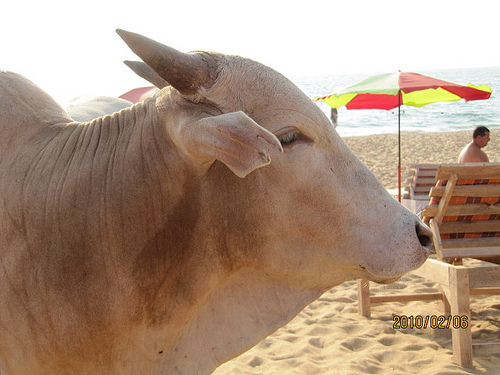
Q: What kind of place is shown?
A: It is a beach.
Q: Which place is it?
A: It is a beach.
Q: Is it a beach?
A: Yes, it is a beach.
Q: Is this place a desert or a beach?
A: It is a beach.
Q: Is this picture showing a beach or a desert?
A: It is showing a beach.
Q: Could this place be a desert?
A: No, it is a beach.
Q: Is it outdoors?
A: Yes, it is outdoors.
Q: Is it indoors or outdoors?
A: It is outdoors.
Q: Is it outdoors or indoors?
A: It is outdoors.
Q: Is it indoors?
A: No, it is outdoors.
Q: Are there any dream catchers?
A: No, there are no dream catchers.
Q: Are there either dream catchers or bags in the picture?
A: No, there are no dream catchers or bags.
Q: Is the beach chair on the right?
A: Yes, the beach chair is on the right of the image.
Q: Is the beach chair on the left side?
A: No, the beach chair is on the right of the image.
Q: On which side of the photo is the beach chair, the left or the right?
A: The beach chair is on the right of the image.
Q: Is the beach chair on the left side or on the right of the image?
A: The beach chair is on the right of the image.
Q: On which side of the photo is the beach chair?
A: The beach chair is on the right of the image.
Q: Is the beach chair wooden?
A: Yes, the beach chair is wooden.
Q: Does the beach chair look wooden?
A: Yes, the beach chair is wooden.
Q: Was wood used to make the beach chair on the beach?
A: Yes, the beach chair is made of wood.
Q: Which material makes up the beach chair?
A: The beach chair is made of wood.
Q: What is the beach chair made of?
A: The beach chair is made of wood.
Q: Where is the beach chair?
A: The beach chair is on the beach.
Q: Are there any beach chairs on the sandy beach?
A: Yes, there is a beach chair on the beach.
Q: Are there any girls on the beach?
A: No, there is a beach chair on the beach.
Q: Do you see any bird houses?
A: No, there are no bird houses.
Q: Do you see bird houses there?
A: No, there are no bird houses.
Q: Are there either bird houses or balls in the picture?
A: No, there are no bird houses or balls.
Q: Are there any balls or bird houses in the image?
A: No, there are no bird houses or balls.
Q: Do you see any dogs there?
A: No, there are no dogs.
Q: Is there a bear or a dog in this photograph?
A: No, there are no dogs or bears.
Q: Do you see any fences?
A: No, there are no fences.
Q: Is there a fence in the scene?
A: No, there are no fences.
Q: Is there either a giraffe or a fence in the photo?
A: No, there are no fences or giraffes.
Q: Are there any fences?
A: No, there are no fences.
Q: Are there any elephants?
A: No, there are no elephants.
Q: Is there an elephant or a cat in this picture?
A: No, there are no elephants or cats.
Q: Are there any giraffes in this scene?
A: No, there are no giraffes.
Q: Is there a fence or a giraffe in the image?
A: No, there are no giraffes or fences.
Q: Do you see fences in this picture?
A: No, there are no fences.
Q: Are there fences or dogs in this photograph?
A: No, there are no fences or dogs.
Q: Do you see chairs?
A: Yes, there is a chair.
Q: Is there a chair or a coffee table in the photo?
A: Yes, there is a chair.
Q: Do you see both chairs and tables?
A: No, there is a chair but no tables.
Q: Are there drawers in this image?
A: No, there are no drawers.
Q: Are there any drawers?
A: No, there are no drawers.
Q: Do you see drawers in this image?
A: No, there are no drawers.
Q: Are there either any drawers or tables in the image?
A: No, there are no drawers or tables.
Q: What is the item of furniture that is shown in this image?
A: The piece of furniture is a chair.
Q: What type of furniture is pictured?
A: The furniture is a chair.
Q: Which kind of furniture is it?
A: The piece of furniture is a chair.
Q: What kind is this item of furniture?
A: This is a chair.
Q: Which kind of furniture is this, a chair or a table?
A: This is a chair.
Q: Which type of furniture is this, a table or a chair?
A: This is a chair.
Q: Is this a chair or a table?
A: This is a chair.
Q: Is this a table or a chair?
A: This is a chair.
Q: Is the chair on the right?
A: Yes, the chair is on the right of the image.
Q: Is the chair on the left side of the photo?
A: No, the chair is on the right of the image.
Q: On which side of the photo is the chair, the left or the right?
A: The chair is on the right of the image.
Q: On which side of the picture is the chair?
A: The chair is on the right of the image.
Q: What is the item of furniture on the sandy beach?
A: The piece of furniture is a chair.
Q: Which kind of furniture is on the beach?
A: The piece of furniture is a chair.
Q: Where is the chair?
A: The chair is on the beach.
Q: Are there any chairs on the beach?
A: Yes, there is a chair on the beach.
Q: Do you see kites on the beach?
A: No, there is a chair on the beach.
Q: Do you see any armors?
A: No, there are no armors.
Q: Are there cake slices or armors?
A: No, there are no armors or cake slices.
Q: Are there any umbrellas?
A: Yes, there is an umbrella.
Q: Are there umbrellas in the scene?
A: Yes, there is an umbrella.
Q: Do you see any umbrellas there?
A: Yes, there is an umbrella.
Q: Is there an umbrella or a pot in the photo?
A: Yes, there is an umbrella.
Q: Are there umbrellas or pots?
A: Yes, there is an umbrella.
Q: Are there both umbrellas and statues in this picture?
A: No, there is an umbrella but no statues.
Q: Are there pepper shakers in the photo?
A: No, there are no pepper shakers.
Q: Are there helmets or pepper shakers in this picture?
A: No, there are no pepper shakers or helmets.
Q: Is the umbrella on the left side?
A: No, the umbrella is on the right of the image.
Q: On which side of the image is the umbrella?
A: The umbrella is on the right of the image.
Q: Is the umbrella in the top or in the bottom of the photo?
A: The umbrella is in the top of the image.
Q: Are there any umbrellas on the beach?
A: Yes, there is an umbrella on the beach.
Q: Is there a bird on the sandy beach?
A: No, there is an umbrella on the beach.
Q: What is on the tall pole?
A: The umbrella is on the pole.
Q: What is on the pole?
A: The umbrella is on the pole.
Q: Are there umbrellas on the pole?
A: Yes, there is an umbrella on the pole.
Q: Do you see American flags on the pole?
A: No, there is an umbrella on the pole.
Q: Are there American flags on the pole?
A: No, there is an umbrella on the pole.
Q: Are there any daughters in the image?
A: No, there are no daughters.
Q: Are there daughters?
A: No, there are no daughters.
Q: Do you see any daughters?
A: No, there are no daughters.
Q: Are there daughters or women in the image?
A: No, there are no daughters or women.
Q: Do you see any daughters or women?
A: No, there are no daughters or women.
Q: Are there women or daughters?
A: No, there are no daughters or women.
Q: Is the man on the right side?
A: Yes, the man is on the right of the image.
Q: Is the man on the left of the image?
A: No, the man is on the right of the image.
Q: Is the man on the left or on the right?
A: The man is on the right of the image.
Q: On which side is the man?
A: The man is on the right of the image.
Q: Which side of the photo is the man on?
A: The man is on the right of the image.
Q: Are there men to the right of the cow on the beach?
A: Yes, there is a man to the right of the cow.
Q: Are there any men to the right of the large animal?
A: Yes, there is a man to the right of the cow.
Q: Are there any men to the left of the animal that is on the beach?
A: No, the man is to the right of the cow.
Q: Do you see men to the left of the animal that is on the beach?
A: No, the man is to the right of the cow.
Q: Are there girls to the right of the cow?
A: No, there is a man to the right of the cow.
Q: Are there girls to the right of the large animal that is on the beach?
A: No, there is a man to the right of the cow.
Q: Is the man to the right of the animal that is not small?
A: Yes, the man is to the right of the cow.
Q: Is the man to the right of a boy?
A: No, the man is to the right of the cow.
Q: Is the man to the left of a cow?
A: No, the man is to the right of a cow.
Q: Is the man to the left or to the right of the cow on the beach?
A: The man is to the right of the cow.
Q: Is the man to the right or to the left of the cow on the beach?
A: The man is to the right of the cow.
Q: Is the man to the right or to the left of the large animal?
A: The man is to the right of the cow.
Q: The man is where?
A: The man is on the beach.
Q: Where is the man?
A: The man is on the beach.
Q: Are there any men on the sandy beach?
A: Yes, there is a man on the beach.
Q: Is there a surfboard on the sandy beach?
A: No, there is a man on the beach.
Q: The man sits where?
A: The man sits on the beach.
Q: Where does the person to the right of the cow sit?
A: The man sits on the beach.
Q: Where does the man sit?
A: The man sits on the beach.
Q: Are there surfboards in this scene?
A: No, there are no surfboards.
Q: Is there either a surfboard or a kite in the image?
A: No, there are no surfboards or kites.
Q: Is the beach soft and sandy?
A: Yes, the beach is soft and sandy.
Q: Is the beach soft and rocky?
A: No, the beach is soft but sandy.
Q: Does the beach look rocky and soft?
A: No, the beach is soft but sandy.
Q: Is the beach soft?
A: Yes, the beach is soft.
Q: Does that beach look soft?
A: Yes, the beach is soft.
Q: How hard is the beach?
A: The beach is soft.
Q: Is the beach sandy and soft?
A: Yes, the beach is sandy and soft.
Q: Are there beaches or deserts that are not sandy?
A: No, there is a beach but it is sandy.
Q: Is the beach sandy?
A: Yes, the beach is sandy.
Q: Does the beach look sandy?
A: Yes, the beach is sandy.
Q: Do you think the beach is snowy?
A: No, the beach is sandy.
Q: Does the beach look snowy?
A: No, the beach is sandy.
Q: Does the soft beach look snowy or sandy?
A: The beach is sandy.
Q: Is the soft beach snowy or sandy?
A: The beach is sandy.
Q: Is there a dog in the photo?
A: No, there are no dogs.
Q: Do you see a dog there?
A: No, there are no dogs.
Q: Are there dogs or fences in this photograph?
A: No, there are no dogs or fences.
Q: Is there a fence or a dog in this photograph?
A: No, there are no dogs or fences.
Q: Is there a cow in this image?
A: Yes, there is a cow.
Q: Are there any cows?
A: Yes, there is a cow.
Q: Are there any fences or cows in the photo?
A: Yes, there is a cow.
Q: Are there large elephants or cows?
A: Yes, there is a large cow.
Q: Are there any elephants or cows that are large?
A: Yes, the cow is large.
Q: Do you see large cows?
A: Yes, there is a large cow.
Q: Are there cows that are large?
A: Yes, there is a cow that is large.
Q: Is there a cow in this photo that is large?
A: Yes, there is a cow that is large.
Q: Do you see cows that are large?
A: Yes, there is a cow that is large.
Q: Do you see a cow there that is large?
A: Yes, there is a cow that is large.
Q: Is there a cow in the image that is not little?
A: Yes, there is a large cow.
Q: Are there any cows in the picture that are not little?
A: Yes, there is a large cow.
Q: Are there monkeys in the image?
A: No, there are no monkeys.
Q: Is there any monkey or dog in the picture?
A: No, there are no monkeys or dogs.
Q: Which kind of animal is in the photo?
A: The animal is a cow.